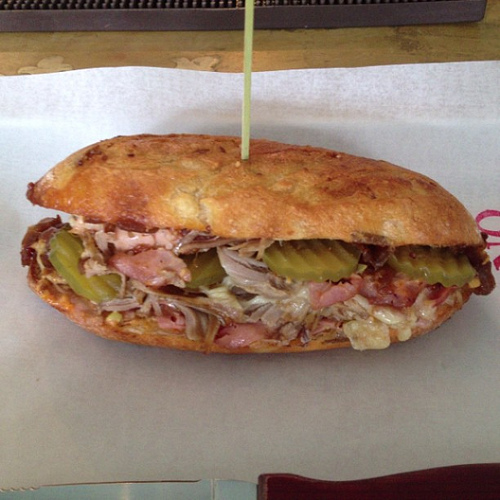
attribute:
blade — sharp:
[0, 477, 257, 499]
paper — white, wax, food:
[36, 76, 477, 496]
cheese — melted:
[363, 299, 436, 346]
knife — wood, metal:
[12, 468, 490, 498]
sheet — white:
[364, 80, 486, 150]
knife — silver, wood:
[0, 460, 500, 498]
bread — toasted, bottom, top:
[31, 124, 482, 251]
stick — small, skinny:
[237, 1, 259, 163]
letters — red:
[465, 205, 496, 271]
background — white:
[425, 365, 487, 426]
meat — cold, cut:
[74, 225, 465, 329]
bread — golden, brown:
[14, 120, 496, 371]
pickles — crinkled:
[46, 214, 471, 318]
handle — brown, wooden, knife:
[255, 459, 484, 494]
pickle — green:
[37, 221, 119, 311]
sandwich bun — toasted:
[73, 130, 424, 280]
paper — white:
[91, 38, 448, 178]